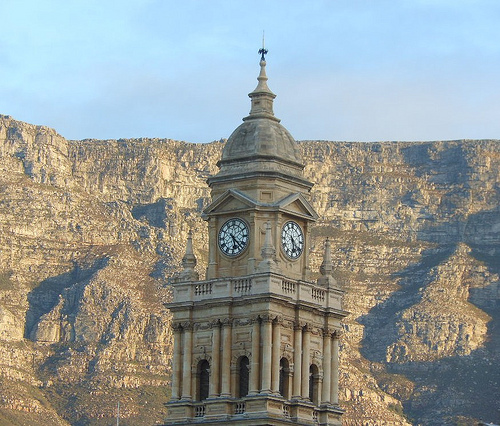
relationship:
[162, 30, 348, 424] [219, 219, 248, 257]
building has a clock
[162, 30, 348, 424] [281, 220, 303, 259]
building has a clock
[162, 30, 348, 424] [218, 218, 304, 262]
building has clocks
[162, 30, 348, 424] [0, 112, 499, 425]
building by mountains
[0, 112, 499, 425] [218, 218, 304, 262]
mountains are behind clocks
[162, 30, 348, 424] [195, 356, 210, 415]
building has archway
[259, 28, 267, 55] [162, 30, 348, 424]
tip of building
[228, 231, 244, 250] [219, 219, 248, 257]
hands of clock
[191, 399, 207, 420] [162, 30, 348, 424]
railing on building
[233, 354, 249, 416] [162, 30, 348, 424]
archway of building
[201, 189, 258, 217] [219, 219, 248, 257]
triangle over clock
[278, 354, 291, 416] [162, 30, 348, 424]
archway in building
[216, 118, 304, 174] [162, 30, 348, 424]
dome on building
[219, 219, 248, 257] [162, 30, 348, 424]
clock on side of building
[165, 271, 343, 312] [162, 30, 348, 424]
parapet on building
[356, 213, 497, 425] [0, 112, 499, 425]
shadow on mountains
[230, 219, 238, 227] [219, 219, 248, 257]
roman numeral on clock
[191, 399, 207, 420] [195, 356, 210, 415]
railing in front of archway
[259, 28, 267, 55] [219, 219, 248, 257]
tip above clock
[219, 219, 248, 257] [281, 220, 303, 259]
clock next to clock